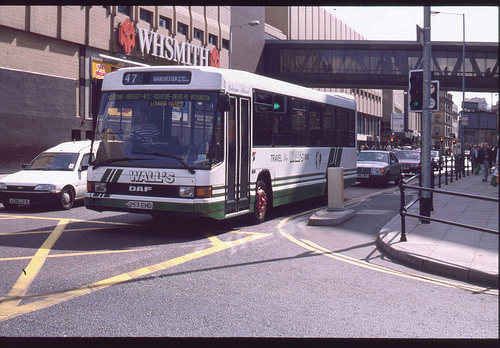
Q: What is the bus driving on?
A: Street.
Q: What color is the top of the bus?
A: White.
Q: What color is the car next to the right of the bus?
A: White.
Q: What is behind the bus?
A: Cars.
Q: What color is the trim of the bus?
A: Green.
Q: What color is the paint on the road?
A: Yellow.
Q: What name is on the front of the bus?
A: Wall's.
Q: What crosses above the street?
A: Walkway.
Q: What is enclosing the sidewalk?
A: Rails.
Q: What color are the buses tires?
A: Black.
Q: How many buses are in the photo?
A: One.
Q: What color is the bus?
A: White, green and black.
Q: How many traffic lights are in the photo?
A: One.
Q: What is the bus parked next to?
A: Sidewalk.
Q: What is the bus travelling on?
A: Street.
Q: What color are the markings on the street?
A: Yellow.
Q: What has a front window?
A: The bus.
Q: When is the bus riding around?
A: During the day.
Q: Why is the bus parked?
A: Red light.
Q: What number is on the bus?
A: 47.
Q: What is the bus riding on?
A: Road way.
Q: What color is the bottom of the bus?
A: Green.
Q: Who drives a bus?
A: Bus driver.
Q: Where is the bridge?
A: Above the bus.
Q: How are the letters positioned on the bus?
A: Side by side.